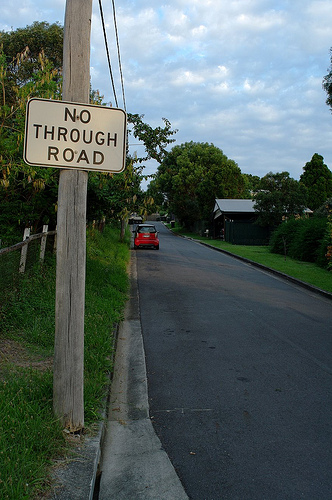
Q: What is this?
A: A road.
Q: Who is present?
A: Noone.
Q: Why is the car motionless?
A: It is parked.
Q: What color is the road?
A: Grey.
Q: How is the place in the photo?
A: Green.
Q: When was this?
A: Daytime.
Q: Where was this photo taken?
A: A Dead End.